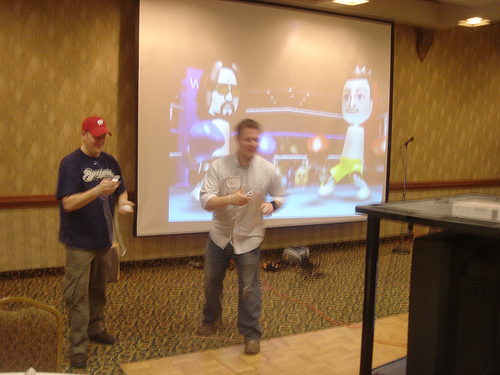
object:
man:
[191, 114, 296, 357]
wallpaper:
[0, 0, 500, 203]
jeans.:
[199, 233, 266, 345]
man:
[50, 110, 139, 370]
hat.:
[80, 115, 114, 138]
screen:
[124, 0, 401, 242]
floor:
[1, 234, 419, 375]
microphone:
[399, 135, 416, 152]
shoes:
[59, 339, 95, 375]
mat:
[118, 310, 419, 375]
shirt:
[191, 150, 295, 261]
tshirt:
[50, 145, 131, 257]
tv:
[400, 230, 500, 374]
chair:
[0, 294, 74, 374]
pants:
[55, 240, 116, 353]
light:
[451, 13, 494, 33]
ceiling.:
[272, 0, 496, 46]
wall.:
[1, 4, 496, 191]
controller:
[243, 190, 257, 198]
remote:
[109, 173, 122, 185]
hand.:
[97, 177, 122, 197]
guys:
[189, 113, 291, 360]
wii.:
[448, 195, 500, 226]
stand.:
[350, 188, 500, 374]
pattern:
[120, 295, 137, 316]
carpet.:
[0, 230, 430, 375]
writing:
[81, 166, 119, 184]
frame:
[0, 294, 72, 375]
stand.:
[396, 145, 412, 247]